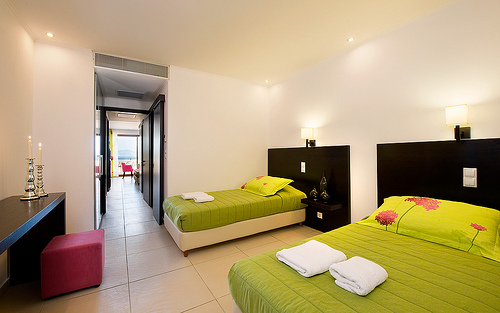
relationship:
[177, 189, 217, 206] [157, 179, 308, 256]
towel on bed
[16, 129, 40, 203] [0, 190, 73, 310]
candle on desk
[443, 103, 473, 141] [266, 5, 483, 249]
light on wall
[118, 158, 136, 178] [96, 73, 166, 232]
chair down hallway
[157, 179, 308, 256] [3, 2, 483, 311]
bed in room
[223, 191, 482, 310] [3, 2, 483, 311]
bed in room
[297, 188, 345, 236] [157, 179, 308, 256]
table beside bed